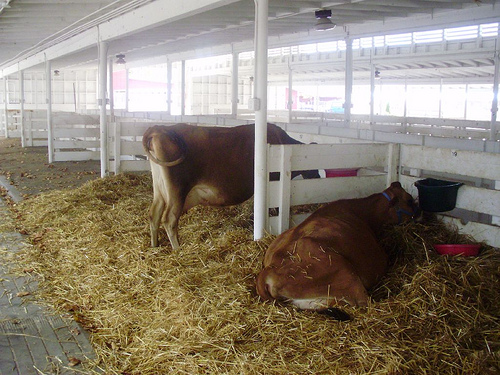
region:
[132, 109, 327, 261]
brown cow eating food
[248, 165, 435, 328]
brown cow laying down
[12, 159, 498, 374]
golden coloured straw for cows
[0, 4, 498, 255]
wooden white painted livestock stalls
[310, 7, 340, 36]
large white light on the ceiling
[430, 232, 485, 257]
red plastic dish for cow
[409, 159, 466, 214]
hanging black plastic dish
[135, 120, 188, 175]
curled brown cow tail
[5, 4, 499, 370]
large well lit barn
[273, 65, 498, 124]
row of sunny windows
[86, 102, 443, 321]
Two cows in a barn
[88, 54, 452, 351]
Two brown cows in a barn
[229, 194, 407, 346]
Cows feet buried in hay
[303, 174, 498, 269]
Red bowl next to a cow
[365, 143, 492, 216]
Black container attached to a cow stall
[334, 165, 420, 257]
Cow with a blue strap around it's face and neck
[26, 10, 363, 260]
Cow standing in a stall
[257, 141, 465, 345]
Cow laying down in a stall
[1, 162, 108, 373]
Hay on the edge of a walkway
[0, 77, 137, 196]
Three empty white stalls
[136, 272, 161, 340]
There is light straw that is beneath the cow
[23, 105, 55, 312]
There are dark gray stones that are visible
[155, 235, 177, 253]
There are feet that are very light brown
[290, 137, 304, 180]
There is white that covers the fence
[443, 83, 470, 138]
There is an open window that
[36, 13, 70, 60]
There is a white ceiling that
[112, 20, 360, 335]
Jackson Mingus is the photographer here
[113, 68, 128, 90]
There is a red barn that is visible there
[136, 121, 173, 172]
There is a tail that is visible here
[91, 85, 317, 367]
This season is the season of summer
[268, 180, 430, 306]
cow lying in stall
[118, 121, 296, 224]
cow standing in stall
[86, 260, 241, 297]
straw on the ground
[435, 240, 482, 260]
pan in front of cow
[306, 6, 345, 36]
light above the cow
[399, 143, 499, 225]
fence area in front of cow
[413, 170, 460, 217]
pail hanging from fence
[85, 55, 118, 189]
pole structure part of enclosure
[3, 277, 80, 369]
concrete ground behind cows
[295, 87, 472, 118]
area outside of cow environment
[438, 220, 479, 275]
A RED BOWL IS IN THE COW PEN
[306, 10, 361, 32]
LIGHT FIXTURES ARE HANGING ABOVE THE COWS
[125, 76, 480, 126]
BRIGHT LIGHT IS SHINING IN FROM THE BACKGROUND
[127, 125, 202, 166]
COWS TAIL IS CURLED UP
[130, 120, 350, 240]
COW IS STANDING UP IN THE HAY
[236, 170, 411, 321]
COW IS LAYING DOWN IN THE HAY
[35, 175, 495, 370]
FRONT PART OF COW PEN IS COVERED IN HAY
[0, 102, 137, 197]
BACK PART OF COW PEN HAS NO COVERING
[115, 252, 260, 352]
HAY IS A GOLDEN YELLOW COLOR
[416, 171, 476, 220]
BLACK BUCKET HANGS FROM THE FENCE